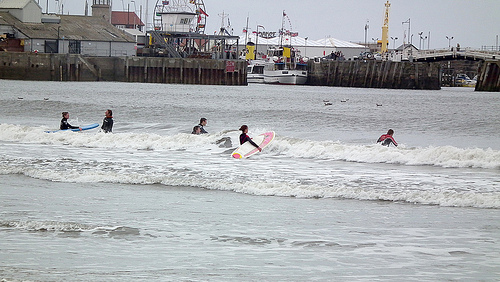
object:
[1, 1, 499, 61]
pier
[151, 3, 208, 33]
ferris wheel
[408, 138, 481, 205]
window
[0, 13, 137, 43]
house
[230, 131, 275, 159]
wheel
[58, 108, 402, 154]
group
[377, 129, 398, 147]
surfer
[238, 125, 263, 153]
surfer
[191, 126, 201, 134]
surfer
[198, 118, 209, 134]
surfer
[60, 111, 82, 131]
surfer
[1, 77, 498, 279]
ocean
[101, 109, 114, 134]
people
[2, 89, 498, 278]
water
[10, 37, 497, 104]
beach